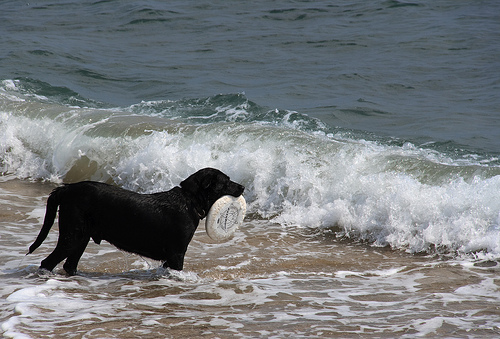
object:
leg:
[171, 253, 185, 271]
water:
[255, 247, 323, 283]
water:
[17, 6, 142, 73]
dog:
[23, 167, 249, 276]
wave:
[299, 120, 499, 253]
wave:
[3, 73, 175, 173]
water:
[5, 2, 500, 70]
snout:
[230, 180, 247, 198]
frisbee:
[205, 187, 247, 244]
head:
[179, 167, 244, 221]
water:
[282, 6, 485, 64]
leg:
[40, 240, 67, 271]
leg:
[64, 244, 88, 274]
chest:
[175, 207, 201, 258]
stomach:
[93, 229, 165, 262]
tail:
[26, 184, 60, 256]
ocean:
[2, 3, 498, 337]